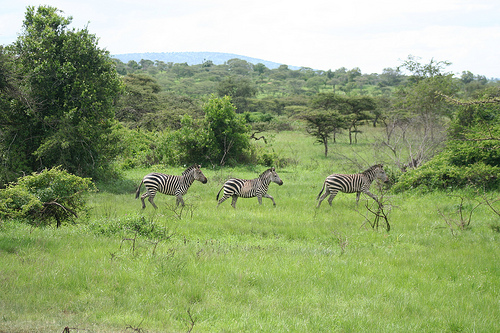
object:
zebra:
[135, 163, 208, 213]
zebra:
[215, 167, 283, 208]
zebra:
[316, 163, 391, 211]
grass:
[2, 129, 500, 333]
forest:
[0, 0, 500, 128]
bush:
[1, 164, 100, 228]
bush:
[176, 95, 263, 169]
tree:
[303, 110, 351, 157]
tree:
[0, 0, 125, 189]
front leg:
[177, 192, 185, 207]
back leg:
[141, 189, 148, 211]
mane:
[135, 165, 207, 210]